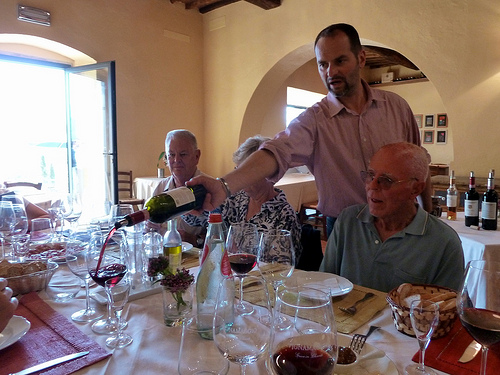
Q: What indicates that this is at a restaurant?
A: The entrance has double doors.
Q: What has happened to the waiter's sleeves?
A: He rolled them up.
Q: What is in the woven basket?
A: Bread.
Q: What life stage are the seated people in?
A: Elderly.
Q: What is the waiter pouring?
A: Red Wine.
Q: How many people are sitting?
A: Four.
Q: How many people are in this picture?
A: Five.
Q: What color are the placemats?
A: Red.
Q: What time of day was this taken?
A: Day time.